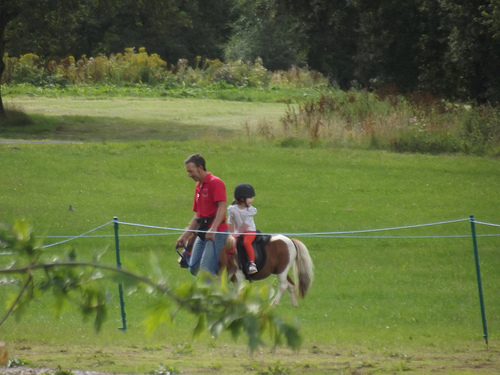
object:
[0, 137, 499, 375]
grass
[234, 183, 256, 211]
helmet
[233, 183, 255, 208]
head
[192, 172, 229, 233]
shirt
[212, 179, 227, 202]
sleeves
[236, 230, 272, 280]
saddle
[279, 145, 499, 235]
lawn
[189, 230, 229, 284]
jeans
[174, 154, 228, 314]
man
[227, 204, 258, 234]
shirt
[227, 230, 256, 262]
leggings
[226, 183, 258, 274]
girl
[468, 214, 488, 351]
pole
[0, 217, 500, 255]
rope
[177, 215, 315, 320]
pony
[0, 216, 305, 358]
branch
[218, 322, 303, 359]
leaf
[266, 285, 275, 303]
leaf